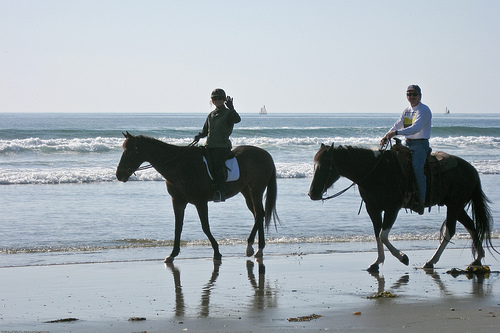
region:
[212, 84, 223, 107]
Eyeglasses in the photo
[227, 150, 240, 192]
A mat on the horse back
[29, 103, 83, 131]
Water in the photo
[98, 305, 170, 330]
Sand in the beach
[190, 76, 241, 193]
A woman riding a horse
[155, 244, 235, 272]
Horse legs in the photo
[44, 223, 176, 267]
Coastline in the photo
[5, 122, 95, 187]
Waves in the ocean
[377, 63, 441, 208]
A man on the horse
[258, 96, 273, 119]
A boat in the ocean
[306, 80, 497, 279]
a man riding a horse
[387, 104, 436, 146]
he is wearing a white shirt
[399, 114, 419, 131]
a yellow design on his shirt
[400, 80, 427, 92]
he is wearing a baseball cap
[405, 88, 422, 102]
he is wearing glasses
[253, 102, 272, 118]
a boat in the water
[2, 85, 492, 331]
the horses are on the beach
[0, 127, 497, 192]
waves in the water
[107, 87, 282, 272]
the woman is riding a horse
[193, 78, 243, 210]
she is holding up her hand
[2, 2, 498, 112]
pale blue daytime sky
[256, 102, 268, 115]
boat with white sails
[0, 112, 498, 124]
surface of calm water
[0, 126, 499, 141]
front of swelling wave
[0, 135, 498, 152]
white water of crashed wave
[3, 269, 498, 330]
wet sand on shore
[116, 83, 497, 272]
two people on horses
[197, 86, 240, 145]
waving woman in helmet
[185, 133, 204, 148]
hand on horse reign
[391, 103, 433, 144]
long sleeved white shirt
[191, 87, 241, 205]
A woman riding a horse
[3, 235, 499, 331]
A wet sandy beach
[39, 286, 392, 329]
some tracks in the sand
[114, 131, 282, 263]
A large brown horse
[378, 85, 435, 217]
A man riding a horse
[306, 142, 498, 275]
A large brown horse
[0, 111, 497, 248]
The ocean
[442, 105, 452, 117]
A boat on the water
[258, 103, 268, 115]
A boat on the water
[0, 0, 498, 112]
A clear blue sky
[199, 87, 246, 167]
this is a boy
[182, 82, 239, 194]
the boy is on the horse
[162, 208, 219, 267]
the legs are long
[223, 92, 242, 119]
the boy is waving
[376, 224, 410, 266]
the leg is folded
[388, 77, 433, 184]
this is a man at the back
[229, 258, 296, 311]
the sand is wet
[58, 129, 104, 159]
the waves are at the sea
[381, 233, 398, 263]
the leg is white in color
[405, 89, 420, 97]
he is wearing goggles